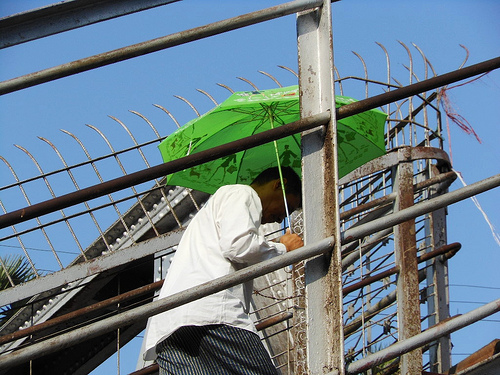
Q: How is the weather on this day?
A: It is clear.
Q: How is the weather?
A: It is clear.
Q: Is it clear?
A: Yes, it is clear.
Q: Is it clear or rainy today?
A: It is clear.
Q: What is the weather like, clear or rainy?
A: It is clear.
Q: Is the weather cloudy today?
A: No, it is clear.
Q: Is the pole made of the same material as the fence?
A: Yes, both the pole and the fence are made of metal.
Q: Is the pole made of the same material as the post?
A: Yes, both the pole and the post are made of metal.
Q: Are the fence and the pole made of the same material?
A: Yes, both the fence and the pole are made of metal.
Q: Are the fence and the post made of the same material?
A: Yes, both the fence and the post are made of metal.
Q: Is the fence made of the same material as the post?
A: Yes, both the fence and the post are made of metal.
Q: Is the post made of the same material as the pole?
A: Yes, both the post and the pole are made of metal.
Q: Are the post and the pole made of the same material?
A: Yes, both the post and the pole are made of metal.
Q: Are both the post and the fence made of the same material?
A: Yes, both the post and the fence are made of metal.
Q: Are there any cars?
A: No, there are no cars.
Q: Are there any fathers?
A: No, there are no fathers.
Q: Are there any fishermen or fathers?
A: No, there are no fathers or fishermen.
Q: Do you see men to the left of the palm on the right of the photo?
A: Yes, there is a man to the left of the palm tree.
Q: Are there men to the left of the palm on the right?
A: Yes, there is a man to the left of the palm tree.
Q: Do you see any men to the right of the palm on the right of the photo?
A: No, the man is to the left of the palm tree.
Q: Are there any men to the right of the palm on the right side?
A: No, the man is to the left of the palm tree.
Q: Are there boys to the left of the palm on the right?
A: No, there is a man to the left of the palm.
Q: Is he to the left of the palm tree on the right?
A: Yes, the man is to the left of the palm tree.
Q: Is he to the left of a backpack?
A: No, the man is to the left of the palm tree.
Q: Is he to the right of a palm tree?
A: No, the man is to the left of a palm tree.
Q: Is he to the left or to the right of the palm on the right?
A: The man is to the left of the palm.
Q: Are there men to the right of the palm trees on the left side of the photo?
A: Yes, there is a man to the right of the palm trees.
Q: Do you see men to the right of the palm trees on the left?
A: Yes, there is a man to the right of the palm trees.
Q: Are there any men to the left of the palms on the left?
A: No, the man is to the right of the palms.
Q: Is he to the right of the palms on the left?
A: Yes, the man is to the right of the palms.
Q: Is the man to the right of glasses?
A: No, the man is to the right of the palms.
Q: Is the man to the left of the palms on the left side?
A: No, the man is to the right of the palm trees.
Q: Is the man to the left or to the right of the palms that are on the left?
A: The man is to the right of the palms.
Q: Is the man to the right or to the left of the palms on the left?
A: The man is to the right of the palms.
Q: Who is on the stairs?
A: The man is on the stairs.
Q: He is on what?
A: The man is on the stairs.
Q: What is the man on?
A: The man is on the stairs.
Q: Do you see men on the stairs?
A: Yes, there is a man on the stairs.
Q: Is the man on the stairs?
A: Yes, the man is on the stairs.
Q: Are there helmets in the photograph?
A: No, there are no helmets.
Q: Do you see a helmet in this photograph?
A: No, there are no helmets.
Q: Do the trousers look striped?
A: Yes, the trousers are striped.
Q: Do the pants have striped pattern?
A: Yes, the pants are striped.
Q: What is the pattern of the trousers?
A: The trousers are striped.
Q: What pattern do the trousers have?
A: The trousers have striped pattern.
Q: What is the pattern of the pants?
A: The trousers are striped.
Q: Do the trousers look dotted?
A: No, the trousers are striped.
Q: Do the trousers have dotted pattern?
A: No, the trousers are striped.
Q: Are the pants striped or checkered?
A: The pants are striped.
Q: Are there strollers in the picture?
A: No, there are no strollers.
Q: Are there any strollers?
A: No, there are no strollers.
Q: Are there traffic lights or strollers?
A: No, there are no strollers or traffic lights.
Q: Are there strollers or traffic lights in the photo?
A: No, there are no strollers or traffic lights.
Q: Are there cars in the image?
A: No, there are no cars.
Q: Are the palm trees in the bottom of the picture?
A: Yes, the palm trees are in the bottom of the image.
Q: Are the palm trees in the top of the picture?
A: No, the palm trees are in the bottom of the image.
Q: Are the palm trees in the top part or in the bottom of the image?
A: The palm trees are in the bottom of the image.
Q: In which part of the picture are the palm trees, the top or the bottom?
A: The palm trees are in the bottom of the image.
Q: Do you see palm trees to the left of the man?
A: Yes, there are palm trees to the left of the man.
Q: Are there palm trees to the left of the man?
A: Yes, there are palm trees to the left of the man.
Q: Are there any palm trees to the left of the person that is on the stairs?
A: Yes, there are palm trees to the left of the man.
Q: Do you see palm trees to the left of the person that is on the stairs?
A: Yes, there are palm trees to the left of the man.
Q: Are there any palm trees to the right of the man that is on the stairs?
A: No, the palm trees are to the left of the man.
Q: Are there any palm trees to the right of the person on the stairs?
A: No, the palm trees are to the left of the man.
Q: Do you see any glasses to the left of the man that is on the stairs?
A: No, there are palm trees to the left of the man.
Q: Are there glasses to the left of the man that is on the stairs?
A: No, there are palm trees to the left of the man.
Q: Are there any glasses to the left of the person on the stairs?
A: No, there are palm trees to the left of the man.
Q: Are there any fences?
A: Yes, there is a fence.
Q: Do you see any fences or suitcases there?
A: Yes, there is a fence.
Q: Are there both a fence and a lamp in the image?
A: No, there is a fence but no lamps.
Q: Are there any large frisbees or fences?
A: Yes, there is a large fence.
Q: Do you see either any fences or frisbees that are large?
A: Yes, the fence is large.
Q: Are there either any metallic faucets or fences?
A: Yes, there is a metal fence.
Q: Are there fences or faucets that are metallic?
A: Yes, the fence is metallic.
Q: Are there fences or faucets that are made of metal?
A: Yes, the fence is made of metal.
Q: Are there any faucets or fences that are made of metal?
A: Yes, the fence is made of metal.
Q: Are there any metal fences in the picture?
A: Yes, there is a metal fence.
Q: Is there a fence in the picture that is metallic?
A: Yes, there is a fence that is metallic.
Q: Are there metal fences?
A: Yes, there is a fence that is made of metal.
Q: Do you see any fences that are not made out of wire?
A: Yes, there is a fence that is made of metal.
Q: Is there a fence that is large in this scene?
A: Yes, there is a large fence.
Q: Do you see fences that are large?
A: Yes, there is a fence that is large.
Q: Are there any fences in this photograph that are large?
A: Yes, there is a fence that is large.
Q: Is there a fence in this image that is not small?
A: Yes, there is a large fence.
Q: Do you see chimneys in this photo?
A: No, there are no chimneys.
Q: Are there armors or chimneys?
A: No, there are no chimneys or armors.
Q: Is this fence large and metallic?
A: Yes, the fence is large and metallic.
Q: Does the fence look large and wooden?
A: No, the fence is large but metallic.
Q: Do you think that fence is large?
A: Yes, the fence is large.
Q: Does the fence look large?
A: Yes, the fence is large.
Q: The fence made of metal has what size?
A: The fence is large.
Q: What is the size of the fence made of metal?
A: The fence is large.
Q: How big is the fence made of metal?
A: The fence is large.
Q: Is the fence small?
A: No, the fence is large.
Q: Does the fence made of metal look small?
A: No, the fence is large.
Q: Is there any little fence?
A: No, there is a fence but it is large.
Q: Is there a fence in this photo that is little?
A: No, there is a fence but it is large.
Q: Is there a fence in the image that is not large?
A: No, there is a fence but it is large.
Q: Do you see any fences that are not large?
A: No, there is a fence but it is large.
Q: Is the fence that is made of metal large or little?
A: The fence is large.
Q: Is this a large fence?
A: Yes, this is a large fence.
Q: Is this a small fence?
A: No, this is a large fence.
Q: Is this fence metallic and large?
A: Yes, the fence is metallic and large.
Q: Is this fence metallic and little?
A: No, the fence is metallic but large.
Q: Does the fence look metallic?
A: Yes, the fence is metallic.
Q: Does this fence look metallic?
A: Yes, the fence is metallic.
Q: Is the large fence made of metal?
A: Yes, the fence is made of metal.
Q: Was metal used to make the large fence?
A: Yes, the fence is made of metal.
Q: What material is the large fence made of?
A: The fence is made of metal.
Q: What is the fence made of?
A: The fence is made of metal.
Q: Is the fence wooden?
A: No, the fence is metallic.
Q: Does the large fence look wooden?
A: No, the fence is metallic.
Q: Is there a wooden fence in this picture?
A: No, there is a fence but it is metallic.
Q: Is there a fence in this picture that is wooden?
A: No, there is a fence but it is metallic.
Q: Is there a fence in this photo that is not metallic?
A: No, there is a fence but it is metallic.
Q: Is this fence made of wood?
A: No, the fence is made of metal.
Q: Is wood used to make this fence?
A: No, the fence is made of metal.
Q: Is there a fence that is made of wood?
A: No, there is a fence but it is made of metal.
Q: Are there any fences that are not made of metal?
A: No, there is a fence but it is made of metal.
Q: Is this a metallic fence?
A: Yes, this is a metallic fence.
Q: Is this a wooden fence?
A: No, this is a metallic fence.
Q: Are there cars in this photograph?
A: No, there are no cars.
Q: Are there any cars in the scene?
A: No, there are no cars.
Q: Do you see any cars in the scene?
A: No, there are no cars.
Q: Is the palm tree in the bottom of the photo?
A: Yes, the palm tree is in the bottom of the image.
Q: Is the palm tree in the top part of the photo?
A: No, the palm tree is in the bottom of the image.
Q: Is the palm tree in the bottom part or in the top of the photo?
A: The palm tree is in the bottom of the image.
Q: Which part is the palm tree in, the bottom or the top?
A: The palm tree is in the bottom of the image.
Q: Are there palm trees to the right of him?
A: Yes, there is a palm tree to the right of the man.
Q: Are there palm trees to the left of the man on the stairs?
A: No, the palm tree is to the right of the man.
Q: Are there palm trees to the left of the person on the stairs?
A: No, the palm tree is to the right of the man.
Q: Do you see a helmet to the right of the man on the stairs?
A: No, there is a palm tree to the right of the man.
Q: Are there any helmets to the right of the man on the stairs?
A: No, there is a palm tree to the right of the man.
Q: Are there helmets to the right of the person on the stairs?
A: No, there is a palm tree to the right of the man.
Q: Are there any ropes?
A: No, there are no ropes.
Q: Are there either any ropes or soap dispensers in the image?
A: No, there are no ropes or soap dispensers.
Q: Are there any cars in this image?
A: No, there are no cars.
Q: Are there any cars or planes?
A: No, there are no cars or planes.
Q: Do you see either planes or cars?
A: No, there are no cars or planes.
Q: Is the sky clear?
A: Yes, the sky is clear.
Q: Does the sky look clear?
A: Yes, the sky is clear.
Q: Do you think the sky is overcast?
A: No, the sky is clear.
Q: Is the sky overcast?
A: No, the sky is clear.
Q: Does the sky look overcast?
A: No, the sky is clear.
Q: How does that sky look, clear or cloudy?
A: The sky is clear.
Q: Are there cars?
A: No, there are no cars.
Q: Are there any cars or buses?
A: No, there are no cars or buses.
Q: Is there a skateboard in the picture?
A: No, there are no skateboards.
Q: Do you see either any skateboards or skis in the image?
A: No, there are no skateboards or skis.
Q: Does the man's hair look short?
A: Yes, the hair is short.